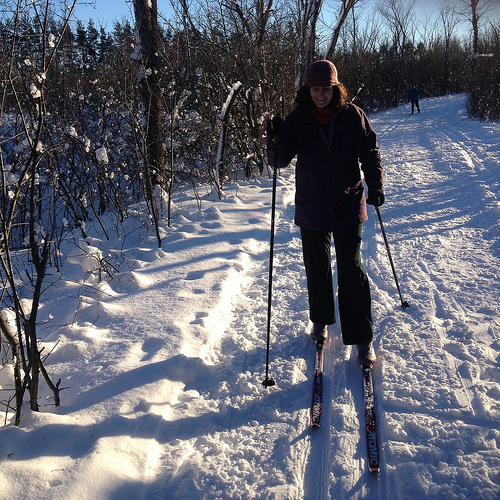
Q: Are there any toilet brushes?
A: No, there are no toilet brushes.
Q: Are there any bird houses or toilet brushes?
A: No, there are no toilet brushes or bird houses.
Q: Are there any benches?
A: No, there are no benches.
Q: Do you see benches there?
A: No, there are no benches.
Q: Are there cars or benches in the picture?
A: No, there are no benches or cars.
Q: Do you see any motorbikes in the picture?
A: No, there are no motorbikes.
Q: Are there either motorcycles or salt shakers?
A: No, there are no motorcycles or salt shakers.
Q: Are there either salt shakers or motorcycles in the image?
A: No, there are no motorcycles or salt shakers.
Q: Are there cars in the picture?
A: No, there are no cars.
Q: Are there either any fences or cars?
A: No, there are no cars or fences.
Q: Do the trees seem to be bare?
A: Yes, the trees are bare.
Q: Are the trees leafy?
A: No, the trees are bare.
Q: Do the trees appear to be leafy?
A: No, the trees are bare.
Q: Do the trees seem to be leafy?
A: No, the trees are bare.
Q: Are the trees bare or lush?
A: The trees are bare.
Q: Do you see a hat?
A: Yes, there is a hat.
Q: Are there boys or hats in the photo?
A: Yes, there is a hat.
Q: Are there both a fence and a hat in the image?
A: No, there is a hat but no fences.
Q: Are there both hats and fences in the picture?
A: No, there is a hat but no fences.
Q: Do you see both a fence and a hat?
A: No, there is a hat but no fences.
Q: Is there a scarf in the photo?
A: Yes, there is a scarf.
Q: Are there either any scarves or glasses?
A: Yes, there is a scarf.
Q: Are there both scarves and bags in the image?
A: No, there is a scarf but no bags.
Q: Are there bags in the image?
A: No, there are no bags.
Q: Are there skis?
A: Yes, there are skis.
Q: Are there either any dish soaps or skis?
A: Yes, there are skis.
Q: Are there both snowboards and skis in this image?
A: No, there are skis but no snowboards.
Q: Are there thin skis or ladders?
A: Yes, there are thin skis.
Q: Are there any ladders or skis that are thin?
A: Yes, the skis are thin.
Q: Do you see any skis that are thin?
A: Yes, there are thin skis.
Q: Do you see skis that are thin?
A: Yes, there are skis that are thin.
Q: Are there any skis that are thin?
A: Yes, there are skis that are thin.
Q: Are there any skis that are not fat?
A: Yes, there are thin skis.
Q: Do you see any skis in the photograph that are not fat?
A: Yes, there are thin skis.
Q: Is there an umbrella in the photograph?
A: No, there are no umbrellas.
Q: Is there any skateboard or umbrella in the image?
A: No, there are no umbrellas or skateboards.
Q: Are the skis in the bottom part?
A: Yes, the skis are in the bottom of the image.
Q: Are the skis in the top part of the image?
A: No, the skis are in the bottom of the image.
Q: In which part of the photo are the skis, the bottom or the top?
A: The skis are in the bottom of the image.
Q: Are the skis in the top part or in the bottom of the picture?
A: The skis are in the bottom of the image.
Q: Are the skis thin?
A: Yes, the skis are thin.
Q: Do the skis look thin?
A: Yes, the skis are thin.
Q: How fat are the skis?
A: The skis are thin.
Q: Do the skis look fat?
A: No, the skis are thin.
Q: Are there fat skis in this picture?
A: No, there are skis but they are thin.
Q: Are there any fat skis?
A: No, there are skis but they are thin.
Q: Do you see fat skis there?
A: No, there are skis but they are thin.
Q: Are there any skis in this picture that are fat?
A: No, there are skis but they are thin.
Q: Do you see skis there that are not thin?
A: No, there are skis but they are thin.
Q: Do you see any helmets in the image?
A: No, there are no helmets.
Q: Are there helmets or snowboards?
A: No, there are no helmets or snowboards.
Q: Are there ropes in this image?
A: No, there are no ropes.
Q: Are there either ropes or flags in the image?
A: No, there are no ropes or flags.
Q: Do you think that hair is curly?
A: Yes, the hair is curly.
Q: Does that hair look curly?
A: Yes, the hair is curly.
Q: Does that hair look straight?
A: No, the hair is curly.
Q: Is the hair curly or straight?
A: The hair is curly.